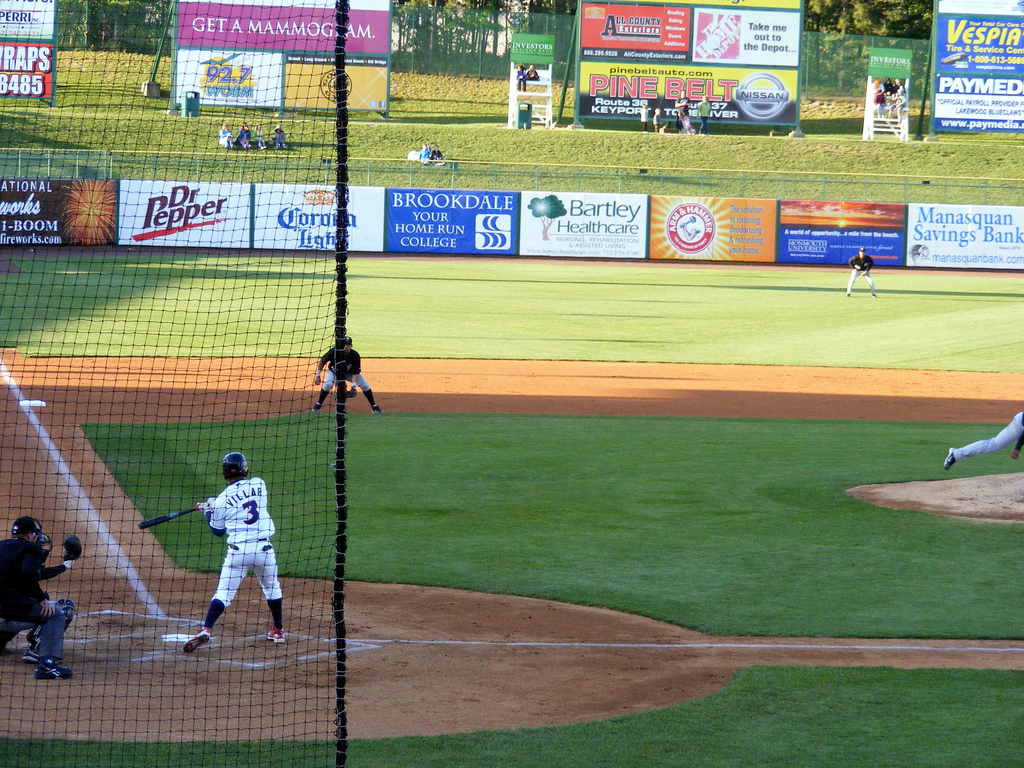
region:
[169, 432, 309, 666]
man wearing a white baseball uniform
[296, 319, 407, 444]
man wearing a black shirt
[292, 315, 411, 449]
man getting ready to pitch the ball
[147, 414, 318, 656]
man getting ready to hit the ball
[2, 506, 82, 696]
man wearing a black helmet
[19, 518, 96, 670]
man holding up a black glove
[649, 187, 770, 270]
yellow and red sign on the fence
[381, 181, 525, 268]
blue and white sign on the fence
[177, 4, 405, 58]
pink sign on the lawn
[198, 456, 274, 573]
black and white jersey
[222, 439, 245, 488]
batter has black helmet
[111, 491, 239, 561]
batter has black bat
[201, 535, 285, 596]
batter has white pants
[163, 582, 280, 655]
batter has long black socks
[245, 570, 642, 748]
white lines on dirt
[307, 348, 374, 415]
fielder has black shirt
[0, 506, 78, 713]
catcher is standing up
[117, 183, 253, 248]
the large sign that says dr pepper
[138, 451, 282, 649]
the player holding the bat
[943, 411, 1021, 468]
the body parts of the pitcher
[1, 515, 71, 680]
the umpire is crouching down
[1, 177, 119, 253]
the sign that has a picture of fireworks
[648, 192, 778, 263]
the sign advertising arm and hammer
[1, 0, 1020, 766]
the large banners facing the baseball field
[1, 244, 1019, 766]
the people standing on the baseball field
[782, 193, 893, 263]
sign on the board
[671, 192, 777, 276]
sign on the board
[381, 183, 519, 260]
sign on the board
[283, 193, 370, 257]
sign on the board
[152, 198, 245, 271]
sign on the board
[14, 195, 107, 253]
sign on the board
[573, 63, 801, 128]
sign on the board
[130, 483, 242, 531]
The player is holding a bat.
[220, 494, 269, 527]
The white jersey have the number 3 on back.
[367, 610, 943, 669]
A white line in the field.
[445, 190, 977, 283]
Advertisements on the fence of the field.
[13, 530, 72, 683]
The umpire is behind the catcher.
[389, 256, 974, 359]
The grass is green.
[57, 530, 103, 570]
The player is wearing a glove.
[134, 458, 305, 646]
a baseball player swinging a bat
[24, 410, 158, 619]
the white line is made of chalk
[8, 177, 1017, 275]
advertisements on a wall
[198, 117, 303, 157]
people sitting on a grassy hill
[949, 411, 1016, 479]
the white pant leg of clothing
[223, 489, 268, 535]
a number on a player's uniform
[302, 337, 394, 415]
a person crouching in the dirt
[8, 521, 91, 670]
a person crouching near the ground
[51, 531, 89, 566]
the catcher's mitt is black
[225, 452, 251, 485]
the person is wearing a helmet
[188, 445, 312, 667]
batter wearing white baseball uniform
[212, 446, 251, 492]
black batting helmet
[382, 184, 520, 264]
Blue sign with white letters reading "Brookdale Your Home Run College"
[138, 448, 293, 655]
Baseball player in white uniform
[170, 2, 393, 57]
Pink sign reading "Get a Mammogram"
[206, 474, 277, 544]
Uniform shirt with blue number 3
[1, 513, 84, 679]
Baseball umpire crouching behind catcher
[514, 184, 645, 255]
White sign advertising Bartley Healthcare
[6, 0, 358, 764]
Wire netting to protect spectators behind home plate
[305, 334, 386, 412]
Baseball player in dark shirt and white pants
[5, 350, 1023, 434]
Dirt base path between second and third bases